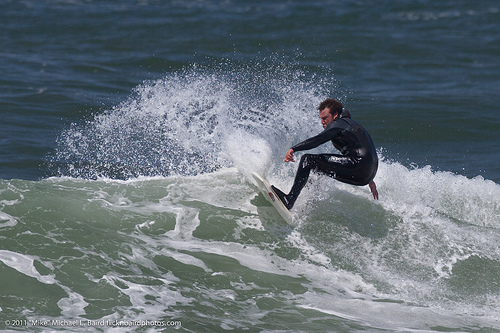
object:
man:
[269, 97, 378, 211]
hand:
[366, 180, 378, 200]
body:
[269, 117, 379, 211]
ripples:
[0, 0, 499, 181]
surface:
[0, 0, 499, 332]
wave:
[0, 40, 499, 332]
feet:
[269, 184, 292, 211]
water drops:
[368, 97, 375, 102]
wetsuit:
[269, 109, 378, 211]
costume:
[286, 117, 378, 203]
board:
[249, 172, 297, 227]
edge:
[249, 172, 264, 183]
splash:
[37, 44, 351, 182]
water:
[0, 0, 499, 332]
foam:
[0, 247, 56, 284]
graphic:
[3, 318, 181, 327]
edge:
[258, 180, 295, 226]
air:
[0, 0, 499, 332]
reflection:
[301, 147, 363, 169]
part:
[34, 269, 56, 285]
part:
[408, 101, 499, 172]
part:
[139, 99, 211, 151]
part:
[87, 320, 117, 326]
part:
[355, 291, 415, 316]